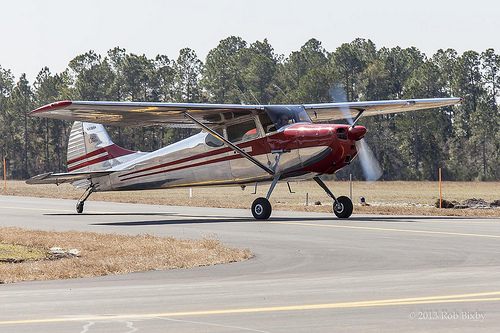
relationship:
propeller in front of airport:
[318, 80, 387, 193] [25, 80, 463, 220]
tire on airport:
[72, 197, 90, 217] [25, 80, 463, 220]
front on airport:
[333, 196, 354, 220] [25, 80, 463, 220]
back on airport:
[74, 200, 84, 213] [25, 80, 463, 220]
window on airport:
[203, 116, 261, 151] [25, 80, 463, 220]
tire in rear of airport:
[72, 197, 90, 217] [25, 80, 463, 220]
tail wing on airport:
[59, 120, 117, 172] [25, 80, 463, 220]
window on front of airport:
[258, 109, 315, 135] [25, 80, 463, 220]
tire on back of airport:
[72, 197, 90, 217] [25, 80, 463, 220]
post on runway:
[432, 164, 449, 211] [4, 192, 498, 332]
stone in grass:
[45, 242, 88, 262] [1, 176, 499, 275]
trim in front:
[253, 202, 265, 216] [333, 196, 354, 220]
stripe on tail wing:
[63, 141, 142, 177] [59, 120, 117, 172]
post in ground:
[432, 164, 449, 211] [429, 190, 500, 214]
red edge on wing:
[24, 96, 73, 120] [26, 95, 257, 128]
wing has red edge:
[26, 95, 257, 128] [24, 96, 73, 120]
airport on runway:
[25, 80, 463, 220] [4, 192, 498, 332]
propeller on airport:
[318, 80, 387, 193] [25, 80, 463, 220]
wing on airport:
[26, 95, 257, 128] [25, 80, 463, 220]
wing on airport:
[308, 91, 467, 126] [25, 80, 463, 220]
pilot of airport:
[265, 109, 296, 136] [25, 80, 463, 220]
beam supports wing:
[180, 110, 277, 181] [26, 95, 257, 128]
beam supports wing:
[348, 111, 363, 127] [308, 91, 467, 126]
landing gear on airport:
[71, 202, 86, 216] [25, 80, 463, 220]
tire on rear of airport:
[72, 197, 90, 217] [25, 80, 463, 220]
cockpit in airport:
[227, 109, 313, 146] [25, 80, 463, 220]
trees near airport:
[0, 32, 499, 187] [1, 85, 500, 332]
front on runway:
[333, 196, 354, 220] [4, 192, 498, 332]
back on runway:
[74, 200, 84, 213] [4, 192, 498, 332]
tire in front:
[72, 197, 90, 217] [243, 180, 361, 227]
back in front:
[74, 200, 84, 213] [243, 180, 361, 227]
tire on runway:
[72, 197, 90, 217] [4, 192, 498, 332]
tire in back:
[72, 197, 90, 217] [63, 189, 105, 220]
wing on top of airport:
[26, 95, 257, 128] [25, 80, 463, 220]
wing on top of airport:
[308, 91, 467, 126] [25, 80, 463, 220]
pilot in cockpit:
[265, 109, 296, 136] [227, 109, 313, 146]